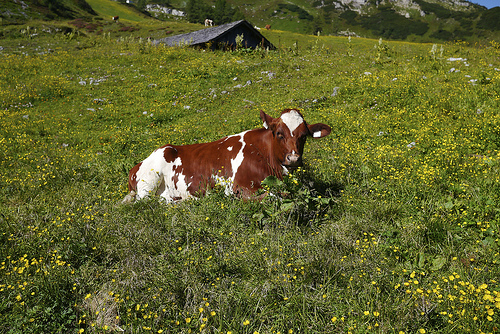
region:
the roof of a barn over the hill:
[155, 20, 280, 53]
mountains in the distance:
[2, 0, 498, 47]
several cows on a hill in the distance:
[110, 17, 272, 28]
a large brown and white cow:
[110, 105, 327, 195]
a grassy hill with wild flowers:
[15, 40, 495, 330]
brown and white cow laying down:
[121, 108, 327, 198]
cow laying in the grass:
[117, 104, 327, 204]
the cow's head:
[259, 110, 327, 165]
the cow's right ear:
[257, 108, 276, 129]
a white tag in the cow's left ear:
[313, 129, 321, 138]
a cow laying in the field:
[97, 58, 354, 232]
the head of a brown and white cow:
[248, 100, 324, 172]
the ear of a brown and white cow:
[249, 101, 286, 130]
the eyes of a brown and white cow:
[278, 123, 301, 144]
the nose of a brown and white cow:
[282, 150, 298, 162]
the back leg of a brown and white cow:
[135, 154, 179, 201]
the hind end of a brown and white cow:
[126, 159, 145, 191]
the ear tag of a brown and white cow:
[312, 120, 322, 141]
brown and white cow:
[121, 105, 333, 205]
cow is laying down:
[121, 108, 333, 205]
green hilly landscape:
[1, 1, 498, 43]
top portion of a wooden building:
[143, 19, 280, 51]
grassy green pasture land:
[1, 26, 498, 328]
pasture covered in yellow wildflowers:
[3, 43, 499, 330]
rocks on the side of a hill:
[142, 2, 185, 19]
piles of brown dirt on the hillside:
[64, 17, 180, 39]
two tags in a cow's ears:
[262, 120, 322, 139]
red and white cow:
[121, 106, 333, 203]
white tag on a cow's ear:
[261, 120, 267, 129]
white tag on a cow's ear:
[312, 129, 320, 136]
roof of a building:
[153, 19, 273, 46]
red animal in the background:
[263, 23, 270, 29]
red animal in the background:
[66, 20, 74, 24]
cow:
[119, 83, 326, 215]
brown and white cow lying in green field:
[97, 82, 329, 232]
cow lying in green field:
[103, 85, 328, 238]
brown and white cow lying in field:
[88, 76, 338, 231]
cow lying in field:
[103, 104, 335, 215]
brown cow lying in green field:
[105, 98, 331, 217]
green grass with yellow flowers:
[26, 153, 69, 190]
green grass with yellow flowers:
[441, 76, 482, 166]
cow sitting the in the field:
[134, 105, 330, 197]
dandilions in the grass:
[431, 273, 481, 313]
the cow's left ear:
[308, 122, 330, 139]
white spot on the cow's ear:
[310, 126, 322, 139]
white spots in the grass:
[405, 137, 415, 151]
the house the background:
[181, 18, 274, 47]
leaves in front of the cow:
[275, 180, 316, 211]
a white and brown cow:
[118, 109, 330, 209]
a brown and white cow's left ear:
[306, 119, 331, 137]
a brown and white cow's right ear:
[259, 109, 274, 130]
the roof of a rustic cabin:
[157, 20, 277, 52]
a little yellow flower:
[15, 293, 22, 300]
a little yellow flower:
[84, 291, 90, 297]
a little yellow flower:
[78, 328, 84, 333]